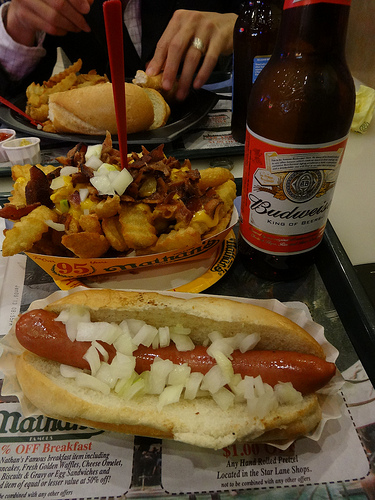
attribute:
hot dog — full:
[3, 289, 343, 437]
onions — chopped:
[67, 311, 280, 404]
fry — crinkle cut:
[1, 209, 63, 259]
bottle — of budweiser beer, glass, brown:
[237, 5, 358, 286]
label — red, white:
[242, 127, 340, 252]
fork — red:
[91, 5, 161, 174]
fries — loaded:
[27, 167, 239, 255]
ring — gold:
[190, 39, 207, 53]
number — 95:
[49, 260, 93, 285]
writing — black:
[246, 195, 334, 225]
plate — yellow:
[58, 194, 241, 292]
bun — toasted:
[37, 359, 303, 460]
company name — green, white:
[0, 406, 120, 451]